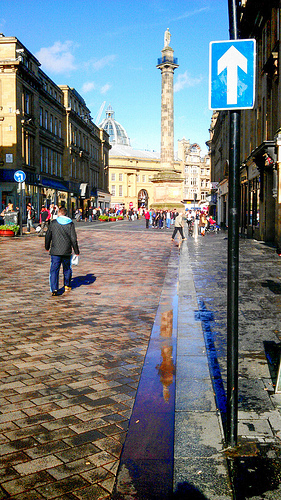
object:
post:
[18, 182, 25, 190]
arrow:
[217, 44, 247, 103]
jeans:
[49, 255, 73, 292]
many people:
[0, 200, 214, 241]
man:
[45, 207, 79, 296]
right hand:
[74, 250, 78, 255]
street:
[0, 217, 181, 498]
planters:
[117, 217, 123, 221]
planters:
[109, 218, 116, 221]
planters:
[99, 218, 107, 222]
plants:
[116, 215, 124, 220]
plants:
[109, 216, 116, 219]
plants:
[99, 215, 109, 219]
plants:
[0, 221, 19, 235]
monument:
[151, 28, 184, 214]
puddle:
[111, 229, 181, 499]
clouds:
[32, 39, 116, 94]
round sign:
[14, 170, 27, 183]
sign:
[208, 39, 257, 111]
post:
[227, 110, 241, 450]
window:
[60, 156, 62, 177]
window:
[46, 147, 49, 175]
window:
[55, 117, 58, 135]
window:
[50, 113, 53, 132]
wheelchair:
[207, 222, 216, 232]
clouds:
[172, 68, 203, 93]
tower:
[149, 25, 184, 216]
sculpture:
[163, 28, 172, 48]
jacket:
[44, 215, 79, 256]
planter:
[0, 229, 15, 236]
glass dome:
[97, 104, 132, 147]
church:
[0, 0, 281, 253]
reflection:
[155, 304, 176, 406]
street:
[7, 227, 208, 493]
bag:
[71, 254, 78, 265]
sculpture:
[162, 385, 170, 405]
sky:
[0, 0, 231, 150]